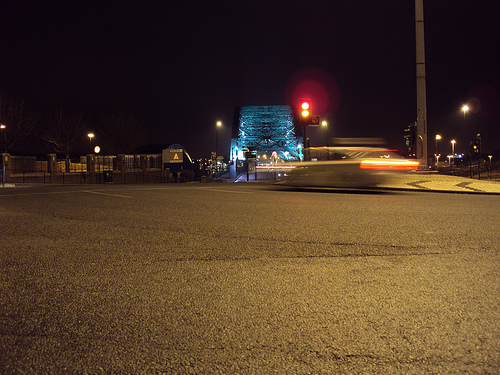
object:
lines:
[0, 184, 269, 199]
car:
[229, 146, 498, 195]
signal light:
[298, 97, 311, 121]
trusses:
[226, 104, 304, 182]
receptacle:
[101, 168, 112, 183]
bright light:
[215, 120, 224, 129]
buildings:
[193, 149, 229, 182]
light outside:
[448, 138, 459, 146]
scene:
[0, 0, 497, 374]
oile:
[300, 117, 307, 147]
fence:
[1, 152, 169, 186]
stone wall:
[228, 105, 308, 183]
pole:
[412, 1, 429, 170]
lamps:
[92, 143, 101, 155]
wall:
[0, 167, 164, 187]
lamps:
[457, 102, 472, 114]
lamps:
[446, 137, 457, 146]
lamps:
[431, 132, 444, 141]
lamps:
[316, 119, 331, 130]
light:
[297, 100, 311, 113]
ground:
[0, 181, 499, 372]